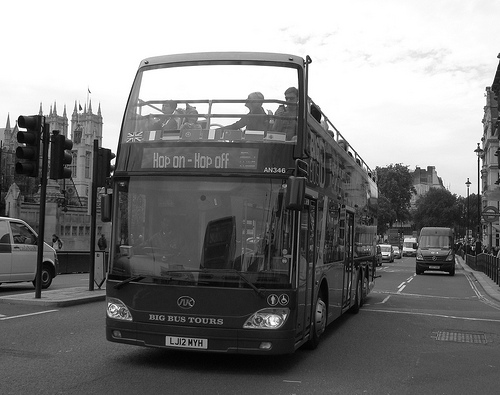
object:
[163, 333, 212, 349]
license plate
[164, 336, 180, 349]
letters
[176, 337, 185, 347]
numbers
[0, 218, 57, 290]
van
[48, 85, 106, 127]
spires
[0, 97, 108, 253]
building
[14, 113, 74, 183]
traffic lights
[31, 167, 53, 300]
pole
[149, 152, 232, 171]
sign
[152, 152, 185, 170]
hop on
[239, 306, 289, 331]
head light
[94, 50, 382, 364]
bus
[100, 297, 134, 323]
head light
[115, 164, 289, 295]
front windshield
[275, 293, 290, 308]
handicap sign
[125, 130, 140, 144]
british flag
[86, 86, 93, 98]
flag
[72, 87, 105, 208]
tower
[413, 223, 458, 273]
van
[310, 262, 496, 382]
road